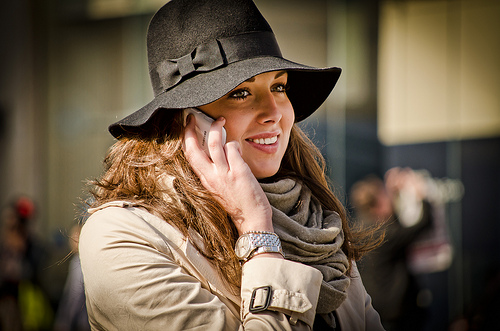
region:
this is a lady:
[80, 4, 361, 329]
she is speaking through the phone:
[166, 100, 232, 161]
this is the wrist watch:
[234, 228, 284, 253]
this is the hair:
[108, 141, 185, 201]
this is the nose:
[259, 100, 285, 122]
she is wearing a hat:
[157, 12, 271, 85]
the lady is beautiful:
[47, 23, 386, 329]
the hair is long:
[99, 137, 184, 206]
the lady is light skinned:
[224, 174, 246, 191]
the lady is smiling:
[247, 126, 284, 152]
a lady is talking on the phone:
[151, 61, 373, 326]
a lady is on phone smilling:
[86, 5, 332, 323]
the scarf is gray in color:
[264, 176, 381, 265]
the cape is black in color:
[157, 24, 269, 93]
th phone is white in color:
[171, 107, 256, 174]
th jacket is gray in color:
[105, 200, 194, 329]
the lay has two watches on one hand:
[240, 229, 299, 284]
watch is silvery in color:
[233, 222, 298, 267]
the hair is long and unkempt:
[123, 148, 247, 320]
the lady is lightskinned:
[198, 147, 246, 227]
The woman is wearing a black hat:
[107, 0, 338, 136]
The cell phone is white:
[182, 105, 222, 142]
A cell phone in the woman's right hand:
[180, 110, 271, 230]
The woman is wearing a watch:
[235, 230, 280, 257]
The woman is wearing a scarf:
[255, 175, 346, 305]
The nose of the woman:
[258, 93, 278, 123]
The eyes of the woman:
[230, 82, 286, 99]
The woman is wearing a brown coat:
[81, 188, 384, 330]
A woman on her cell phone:
[78, 2, 383, 330]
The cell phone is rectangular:
[184, 107, 226, 147]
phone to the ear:
[168, 109, 240, 158]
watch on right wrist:
[216, 226, 273, 256]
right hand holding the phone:
[177, 109, 257, 232]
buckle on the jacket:
[252, 283, 321, 327]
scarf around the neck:
[272, 185, 354, 283]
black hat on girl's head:
[139, 19, 336, 73]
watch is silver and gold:
[228, 228, 283, 250]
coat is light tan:
[90, 234, 315, 330]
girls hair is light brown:
[104, 141, 194, 215]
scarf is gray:
[280, 187, 348, 282]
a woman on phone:
[67, 2, 396, 329]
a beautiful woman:
[64, 0, 391, 330]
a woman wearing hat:
[71, 0, 392, 328]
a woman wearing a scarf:
[69, 1, 388, 329]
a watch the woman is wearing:
[231, 232, 283, 262]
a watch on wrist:
[231, 229, 286, 262]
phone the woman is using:
[177, 108, 227, 158]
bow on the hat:
[151, 32, 231, 96]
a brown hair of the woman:
[91, 131, 235, 249]